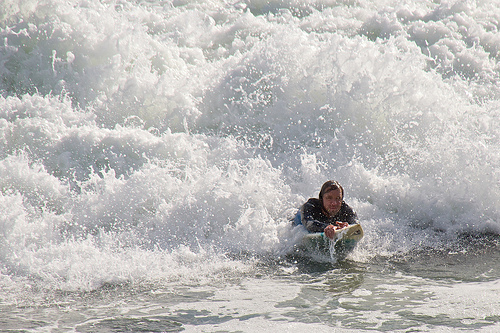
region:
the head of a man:
[318, 179, 348, 216]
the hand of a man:
[321, 220, 338, 242]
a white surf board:
[303, 220, 368, 252]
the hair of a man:
[318, 176, 345, 198]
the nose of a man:
[329, 197, 337, 205]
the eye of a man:
[322, 192, 335, 202]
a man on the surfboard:
[282, 176, 366, 246]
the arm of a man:
[296, 199, 336, 236]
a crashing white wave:
[1, 0, 499, 293]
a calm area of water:
[1, 232, 498, 331]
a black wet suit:
[286, 195, 359, 236]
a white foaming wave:
[0, 0, 499, 297]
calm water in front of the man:
[0, 234, 499, 331]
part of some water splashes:
[276, 42, 335, 80]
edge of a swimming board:
[328, 211, 359, 247]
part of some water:
[403, 272, 450, 323]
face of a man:
[321, 178, 343, 208]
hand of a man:
[326, 223, 344, 245]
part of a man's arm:
[303, 215, 337, 247]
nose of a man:
[327, 195, 339, 210]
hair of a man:
[321, 173, 346, 188]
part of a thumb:
[333, 216, 341, 230]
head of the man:
[328, 183, 339, 200]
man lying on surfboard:
[285, 168, 366, 269]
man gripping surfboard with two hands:
[283, 178, 365, 266]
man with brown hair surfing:
[289, 162, 366, 275]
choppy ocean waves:
[21, 171, 200, 323]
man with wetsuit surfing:
[287, 166, 366, 269]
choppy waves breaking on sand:
[51, 243, 233, 320]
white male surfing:
[278, 173, 370, 272]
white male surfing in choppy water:
[276, 143, 374, 275]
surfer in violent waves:
[191, 153, 407, 304]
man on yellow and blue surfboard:
[263, 167, 390, 279]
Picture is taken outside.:
[17, 11, 482, 311]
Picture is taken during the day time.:
[35, 10, 475, 297]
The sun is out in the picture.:
[23, 16, 460, 163]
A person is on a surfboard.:
[256, 166, 377, 256]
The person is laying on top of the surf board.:
[271, 166, 375, 273]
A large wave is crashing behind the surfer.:
[38, 19, 452, 185]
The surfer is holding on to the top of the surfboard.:
[308, 215, 359, 245]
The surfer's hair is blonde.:
[315, 179, 347, 215]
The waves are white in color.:
[43, 51, 413, 138]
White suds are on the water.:
[214, 276, 499, 325]